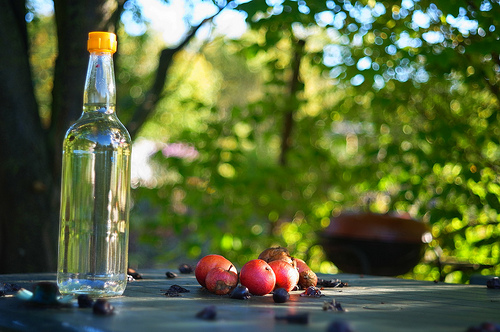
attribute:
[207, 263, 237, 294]
apple — small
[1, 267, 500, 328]
table — gray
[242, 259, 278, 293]
apple — small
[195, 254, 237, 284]
apple — small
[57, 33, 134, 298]
bottle — clear, glass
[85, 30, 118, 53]
cap — yellow, orange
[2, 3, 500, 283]
tree — big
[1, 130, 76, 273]
trunk — long, large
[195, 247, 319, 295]
fruit — small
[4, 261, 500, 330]
berries — scattered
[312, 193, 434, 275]
grill — barbeque, charcoal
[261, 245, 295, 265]
apple — rotten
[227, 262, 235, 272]
stem — brown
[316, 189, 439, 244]
lid — red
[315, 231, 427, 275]
bottom — black